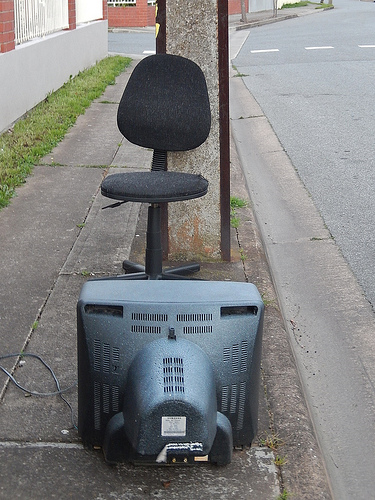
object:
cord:
[1, 347, 74, 437]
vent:
[170, 308, 225, 326]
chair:
[101, 51, 214, 279]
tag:
[160, 417, 186, 437]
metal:
[213, 4, 240, 270]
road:
[218, 0, 373, 496]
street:
[250, 26, 372, 274]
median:
[2, 45, 129, 204]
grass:
[0, 130, 19, 187]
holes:
[132, 307, 214, 334]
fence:
[1, 17, 109, 130]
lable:
[160, 415, 185, 435]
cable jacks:
[165, 443, 205, 466]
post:
[156, 2, 241, 253]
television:
[72, 278, 262, 468]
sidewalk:
[9, 55, 183, 361]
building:
[1, 1, 110, 128]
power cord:
[1, 348, 66, 430]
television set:
[68, 278, 271, 468]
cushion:
[110, 63, 258, 182]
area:
[137, 37, 369, 56]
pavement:
[264, 222, 371, 499]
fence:
[7, 5, 88, 30]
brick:
[5, 7, 17, 49]